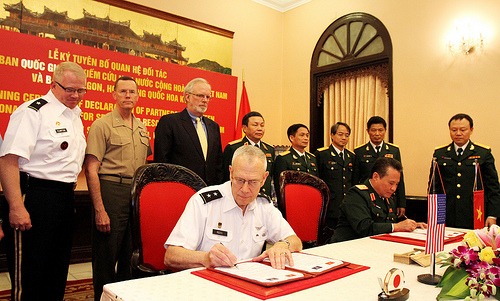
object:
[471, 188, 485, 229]
chinese flag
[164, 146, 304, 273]
man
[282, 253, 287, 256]
ring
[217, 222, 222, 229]
patch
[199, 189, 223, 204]
patch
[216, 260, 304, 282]
papers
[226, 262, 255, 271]
signed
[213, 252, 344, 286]
book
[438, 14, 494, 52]
bright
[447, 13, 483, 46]
light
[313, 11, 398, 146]
set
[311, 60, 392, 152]
wall mirrors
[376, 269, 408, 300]
ornament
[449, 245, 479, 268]
flowers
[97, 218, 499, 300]
table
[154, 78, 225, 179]
diplomats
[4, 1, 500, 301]
room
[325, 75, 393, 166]
curtain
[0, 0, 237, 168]
sign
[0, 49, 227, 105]
foreign language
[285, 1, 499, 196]
walls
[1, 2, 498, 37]
ceiling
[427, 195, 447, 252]
flag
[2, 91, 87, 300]
army uniform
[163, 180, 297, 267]
army uniform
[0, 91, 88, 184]
shirt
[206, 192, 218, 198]
two stars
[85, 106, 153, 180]
shirt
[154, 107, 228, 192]
jacket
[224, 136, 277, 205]
jacket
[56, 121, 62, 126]
patch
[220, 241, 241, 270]
pen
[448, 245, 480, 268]
flower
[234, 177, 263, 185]
glasses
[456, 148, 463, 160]
tie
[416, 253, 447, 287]
stand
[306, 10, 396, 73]
top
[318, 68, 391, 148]
widow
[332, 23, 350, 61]
window